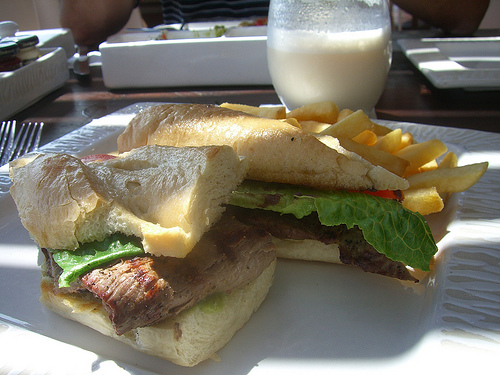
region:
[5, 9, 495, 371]
sandwich on a plate with fries and a drink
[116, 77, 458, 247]
sandwich on a plate with fries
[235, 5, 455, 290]
sandwich on a plate with a drink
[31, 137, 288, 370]
sandwich on a white plate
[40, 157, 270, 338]
green lettuce in a sandwich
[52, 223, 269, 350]
meat in a white roll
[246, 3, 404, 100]
white drink with froth in a clear glass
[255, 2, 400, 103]
white drink with froth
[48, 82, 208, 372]
sandwich plate on a wooden table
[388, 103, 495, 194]
part of fries on a white plate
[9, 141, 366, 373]
The steak sandwich is on the white plate.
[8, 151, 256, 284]
The bread is on top of the lettuce.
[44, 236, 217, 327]
The lettuce is on top of the steak.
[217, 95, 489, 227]
The French fries are next to the sandwich.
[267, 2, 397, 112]
The glass has milk inside.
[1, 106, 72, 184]
Two forks are next to the plate of food.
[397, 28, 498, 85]
The tray is empty.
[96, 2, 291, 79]
This tray is almost empty.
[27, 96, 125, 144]
The table is brown.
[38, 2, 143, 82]
The man's elbows are on top of the table.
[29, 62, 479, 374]
a sandwich on a table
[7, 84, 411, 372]
a made sandwich on a plate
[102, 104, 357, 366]
a sandwich on a white plate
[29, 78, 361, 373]
a plate with a sandwich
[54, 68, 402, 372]
a white plate with a sandwich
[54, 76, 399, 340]
a sandwich cut in half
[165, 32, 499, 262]
french fires on a plate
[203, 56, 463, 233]
french fries on a white plate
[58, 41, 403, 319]
a sandwich and fries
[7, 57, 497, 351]
fries and a sandwich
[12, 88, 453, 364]
sandwich on white plate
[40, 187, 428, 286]
pieces of lettuce on the sandwich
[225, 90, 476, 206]
french fries on white plate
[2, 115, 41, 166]
two forks beside white plate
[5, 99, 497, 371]
square white plate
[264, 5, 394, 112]
glass cup with milk in it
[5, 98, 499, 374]
sunlight on the white plate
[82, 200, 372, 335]
meat on the sandwich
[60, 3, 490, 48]
person sitting at the table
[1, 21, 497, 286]
table person is sitting at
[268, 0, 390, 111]
a clear glass of milk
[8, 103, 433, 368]
two halves of a sandwich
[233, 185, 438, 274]
a piece of green lettuce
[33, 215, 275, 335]
a piece of fried meat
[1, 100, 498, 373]
a square white plate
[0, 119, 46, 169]
two metal silver forks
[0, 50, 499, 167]
a brown wooden table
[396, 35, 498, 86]
an empty white plate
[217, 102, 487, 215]
tan colored french fries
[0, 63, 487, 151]
shadows on a table